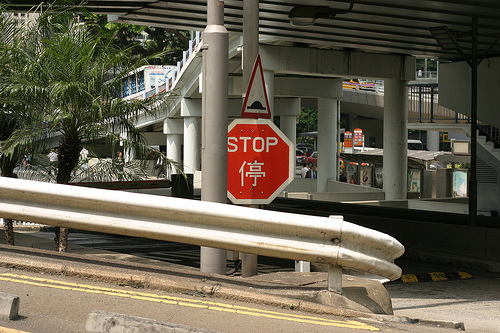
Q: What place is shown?
A: It is a street.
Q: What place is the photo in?
A: It is at the street.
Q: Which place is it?
A: It is a street.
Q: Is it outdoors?
A: Yes, it is outdoors.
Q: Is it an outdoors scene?
A: Yes, it is outdoors.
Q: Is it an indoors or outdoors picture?
A: It is outdoors.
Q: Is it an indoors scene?
A: No, it is outdoors.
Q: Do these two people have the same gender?
A: No, they are both male and female.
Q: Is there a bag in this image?
A: No, there are no bags.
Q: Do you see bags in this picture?
A: No, there are no bags.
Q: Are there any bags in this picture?
A: No, there are no bags.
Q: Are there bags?
A: No, there are no bags.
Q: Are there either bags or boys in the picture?
A: No, there are no bags or boys.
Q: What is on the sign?
A: The character is on the sign.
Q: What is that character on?
A: The character is on the sign.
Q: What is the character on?
A: The character is on the sign.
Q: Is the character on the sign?
A: Yes, the character is on the sign.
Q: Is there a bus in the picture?
A: Yes, there is a bus.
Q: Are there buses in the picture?
A: Yes, there is a bus.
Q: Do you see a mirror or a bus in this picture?
A: Yes, there is a bus.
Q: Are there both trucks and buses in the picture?
A: No, there is a bus but no trucks.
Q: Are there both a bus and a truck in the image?
A: No, there is a bus but no trucks.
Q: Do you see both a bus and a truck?
A: No, there is a bus but no trucks.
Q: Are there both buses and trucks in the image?
A: No, there is a bus but no trucks.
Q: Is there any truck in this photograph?
A: No, there are no trucks.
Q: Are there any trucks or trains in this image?
A: No, there are no trucks or trains.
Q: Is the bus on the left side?
A: Yes, the bus is on the left of the image.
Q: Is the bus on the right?
A: No, the bus is on the left of the image.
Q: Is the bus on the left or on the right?
A: The bus is on the left of the image.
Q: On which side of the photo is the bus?
A: The bus is on the left of the image.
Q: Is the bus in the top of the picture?
A: Yes, the bus is in the top of the image.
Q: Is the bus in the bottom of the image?
A: No, the bus is in the top of the image.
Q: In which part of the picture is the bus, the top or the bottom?
A: The bus is in the top of the image.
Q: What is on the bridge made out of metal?
A: The bus is on the bridge.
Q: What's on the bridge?
A: The bus is on the bridge.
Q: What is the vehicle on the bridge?
A: The vehicle is a bus.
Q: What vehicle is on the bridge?
A: The vehicle is a bus.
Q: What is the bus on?
A: The bus is on the bridge.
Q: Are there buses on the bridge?
A: Yes, there is a bus on the bridge.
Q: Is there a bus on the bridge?
A: Yes, there is a bus on the bridge.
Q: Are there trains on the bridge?
A: No, there is a bus on the bridge.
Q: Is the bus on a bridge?
A: Yes, the bus is on a bridge.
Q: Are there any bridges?
A: Yes, there is a bridge.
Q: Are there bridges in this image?
A: Yes, there is a bridge.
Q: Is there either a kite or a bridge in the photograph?
A: Yes, there is a bridge.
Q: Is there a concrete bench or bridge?
A: Yes, there is a concrete bridge.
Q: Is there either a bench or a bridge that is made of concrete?
A: Yes, the bridge is made of concrete.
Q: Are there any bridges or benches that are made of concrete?
A: Yes, the bridge is made of concrete.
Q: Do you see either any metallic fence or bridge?
A: Yes, there is a metal bridge.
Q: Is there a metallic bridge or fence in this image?
A: Yes, there is a metal bridge.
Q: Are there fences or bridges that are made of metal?
A: Yes, the bridge is made of metal.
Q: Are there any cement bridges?
A: Yes, there is a bridge that is made of cement.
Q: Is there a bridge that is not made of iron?
A: Yes, there is a bridge that is made of concrete.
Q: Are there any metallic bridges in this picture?
A: Yes, there is a metal bridge.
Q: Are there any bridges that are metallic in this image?
A: Yes, there is a metal bridge.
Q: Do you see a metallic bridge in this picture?
A: Yes, there is a metal bridge.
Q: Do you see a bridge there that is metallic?
A: Yes, there is a bridge that is metallic.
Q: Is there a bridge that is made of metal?
A: Yes, there is a bridge that is made of metal.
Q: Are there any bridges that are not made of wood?
A: Yes, there is a bridge that is made of metal.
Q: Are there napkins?
A: No, there are no napkins.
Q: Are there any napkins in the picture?
A: No, there are no napkins.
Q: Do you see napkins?
A: No, there are no napkins.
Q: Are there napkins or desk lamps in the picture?
A: No, there are no napkins or desk lamps.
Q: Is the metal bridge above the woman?
A: Yes, the bridge is above the woman.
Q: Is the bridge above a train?
A: No, the bridge is above the woman.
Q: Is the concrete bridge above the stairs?
A: Yes, the bridge is above the stairs.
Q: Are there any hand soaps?
A: No, there are no hand soaps.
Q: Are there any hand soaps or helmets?
A: No, there are no hand soaps or helmets.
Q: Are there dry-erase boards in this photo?
A: No, there are no dry-erase boards.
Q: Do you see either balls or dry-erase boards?
A: No, there are no dry-erase boards or balls.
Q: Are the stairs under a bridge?
A: Yes, the stairs are under a bridge.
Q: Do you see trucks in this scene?
A: No, there are no trucks.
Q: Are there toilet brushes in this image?
A: No, there are no toilet brushes.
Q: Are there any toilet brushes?
A: No, there are no toilet brushes.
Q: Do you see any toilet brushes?
A: No, there are no toilet brushes.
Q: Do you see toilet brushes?
A: No, there are no toilet brushes.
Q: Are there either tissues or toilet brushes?
A: No, there are no toilet brushes or tissues.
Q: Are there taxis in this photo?
A: Yes, there is a taxi.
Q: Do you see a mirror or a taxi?
A: Yes, there is a taxi.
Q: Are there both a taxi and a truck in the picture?
A: No, there is a taxi but no trucks.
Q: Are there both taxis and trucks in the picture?
A: No, there is a taxi but no trucks.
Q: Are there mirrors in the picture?
A: No, there are no mirrors.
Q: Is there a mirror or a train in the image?
A: No, there are no mirrors or trains.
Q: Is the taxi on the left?
A: No, the taxi is on the right of the image.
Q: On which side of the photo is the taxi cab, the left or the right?
A: The taxi cab is on the right of the image.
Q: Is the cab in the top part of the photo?
A: Yes, the cab is in the top of the image.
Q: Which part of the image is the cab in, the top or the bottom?
A: The cab is in the top of the image.